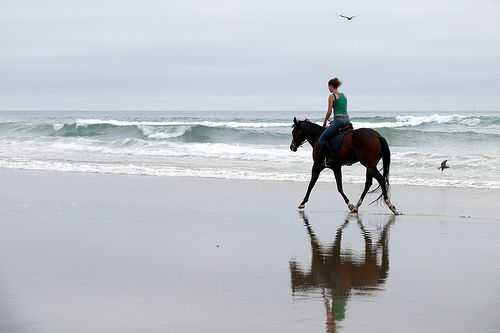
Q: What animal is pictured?
A: Horse.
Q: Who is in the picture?
A: A woman.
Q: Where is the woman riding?
A: A beach.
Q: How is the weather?
A: Calm and overcast.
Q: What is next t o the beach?
A: Ocean.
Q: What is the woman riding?
A: A horse.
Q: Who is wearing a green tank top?
A: The woman.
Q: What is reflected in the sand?
A: The horse.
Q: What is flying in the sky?
A: A bird.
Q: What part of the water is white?
A: The wave.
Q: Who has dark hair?
A: The woman.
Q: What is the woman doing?
A: Riding a horse.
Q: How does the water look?
A: The water is rolling.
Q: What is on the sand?
A: Water.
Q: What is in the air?
A: A bird.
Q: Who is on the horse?
A: A woman.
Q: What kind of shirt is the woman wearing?
A: Sleeveless.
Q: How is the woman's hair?
A: In a ponytail.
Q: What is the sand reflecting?
A: The woman and the horse.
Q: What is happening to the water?
A: Ocean water beginning to receed.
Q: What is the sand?
A: Wet, untouched sand of a beach.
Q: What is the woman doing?
A: Woman riding a horse in front of ocean.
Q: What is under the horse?
A: Shadow of a woman and a horse.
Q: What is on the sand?
A: Shadow cast on wet sand.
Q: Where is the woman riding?
A: Woman riding to the left.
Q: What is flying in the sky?
A: Bird flies in an overcast sky.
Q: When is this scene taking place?
A: Daylight.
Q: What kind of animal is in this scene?
A: Horse.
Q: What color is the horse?
A: Brown.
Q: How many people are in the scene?
A: One.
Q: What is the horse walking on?
A: Sand.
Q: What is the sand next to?
A: Ocean.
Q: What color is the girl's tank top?
A: Green.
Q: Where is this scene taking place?
A: At the beach horseback riding.